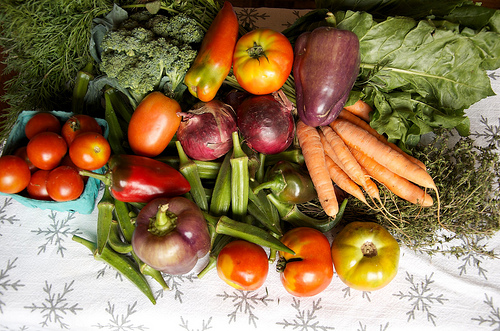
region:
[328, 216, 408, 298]
AN UNRIPE TOMATO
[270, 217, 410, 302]
A GREEN AND A RED TOMATO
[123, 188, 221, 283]
A PURPLE COLORED PEPPER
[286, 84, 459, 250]
A BUNDLE OF NINE CARROTS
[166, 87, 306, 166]
TWO PURPLE ONIONS SIDE BY SIDE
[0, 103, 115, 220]
A SMALL CONTAINER OF TOMATOS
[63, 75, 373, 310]
A PILE OF MANY PIECES OF OKRA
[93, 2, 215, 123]
MULTIPLE STALKS OF BROCOLLI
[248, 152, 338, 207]
A GREEN AND REDDISH JALEPENO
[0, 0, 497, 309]
A DECORATIVE DISPLAY OF GARDEN VEGETABLES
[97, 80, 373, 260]
A variety of vegetables.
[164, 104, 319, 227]
A variety of vegetables.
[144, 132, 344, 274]
A variety of vegetables.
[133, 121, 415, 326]
A variety of vegetables.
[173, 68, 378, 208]
A variety of vegetables.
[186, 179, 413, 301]
A variety of vegetables.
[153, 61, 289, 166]
A variety of vegetables.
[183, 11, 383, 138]
A variety of vegetables.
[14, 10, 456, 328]
many colored vegetables in photo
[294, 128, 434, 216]
bunch of orange carrots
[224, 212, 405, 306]
three tomatoes in photo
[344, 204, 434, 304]
one green tomato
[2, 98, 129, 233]
green basket of cherry tomatoes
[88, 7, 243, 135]
bunch of brocolli near hot pepper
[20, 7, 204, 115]
green vegetables on left hand side of photo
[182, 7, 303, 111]
hot pepper next to tomato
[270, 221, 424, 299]
green tomato next to red tomato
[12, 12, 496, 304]
vegetables on white table cloth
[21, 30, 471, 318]
assorted vegetables and herbs on a tablecloth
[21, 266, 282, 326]
grey snowflakes on a white background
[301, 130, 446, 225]
long and thick carrots with roots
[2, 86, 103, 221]
small tomatoes in green container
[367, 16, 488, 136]
leafy green vegetable with thick vein in middle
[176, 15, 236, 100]
red pepper with green and yellow spots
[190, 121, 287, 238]
long and ridged green okra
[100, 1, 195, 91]
green florets of broccoli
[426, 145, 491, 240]
curved and long sprigs of rosemary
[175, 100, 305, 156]
two red onions side by side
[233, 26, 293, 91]
medium red heirloom tomato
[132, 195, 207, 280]
plum-colored bell pepper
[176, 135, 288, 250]
bunch of green okra pods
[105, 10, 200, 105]
medium head of broccoli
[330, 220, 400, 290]
plump yellow heirloom tomato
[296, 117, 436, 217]
bunch of carrots with green tops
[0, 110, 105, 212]
green carton of tomatoes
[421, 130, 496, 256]
bunch of thyme herb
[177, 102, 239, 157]
onion with red skin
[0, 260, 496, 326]
snowflake patterned table cloth